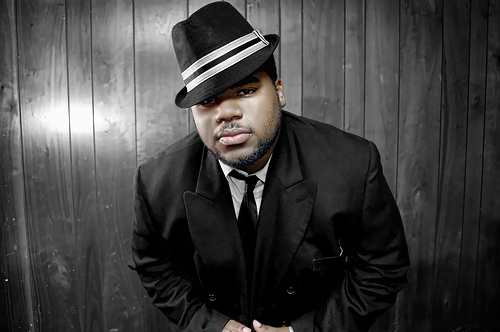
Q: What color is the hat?
A: Black.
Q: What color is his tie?
A: Black.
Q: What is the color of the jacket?
A: Black.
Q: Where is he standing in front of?
A: The wall.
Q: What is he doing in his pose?
A: Leaning.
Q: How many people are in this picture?
A: 1.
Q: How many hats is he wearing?
A: 1.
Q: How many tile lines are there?
A: 14.